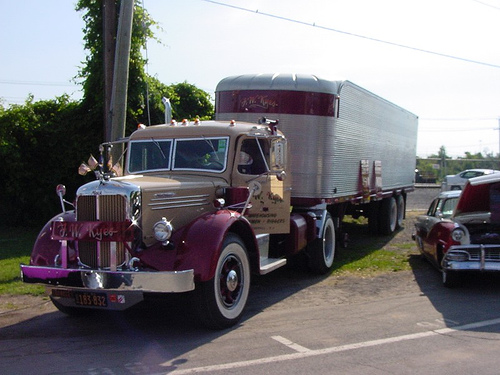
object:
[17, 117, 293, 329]
tractor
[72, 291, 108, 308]
plates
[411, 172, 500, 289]
classic car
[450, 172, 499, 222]
hood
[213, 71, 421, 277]
trailer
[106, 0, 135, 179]
poles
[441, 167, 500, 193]
car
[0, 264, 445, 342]
dirt patch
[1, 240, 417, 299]
grass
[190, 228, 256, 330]
driver's steer tire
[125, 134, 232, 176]
split windshield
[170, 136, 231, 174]
left pane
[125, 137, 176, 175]
right pane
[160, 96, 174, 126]
exhaust pipe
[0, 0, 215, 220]
vines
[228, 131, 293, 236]
open door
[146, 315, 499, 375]
parking lines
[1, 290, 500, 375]
tarmac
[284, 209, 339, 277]
drive tire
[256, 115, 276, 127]
air horn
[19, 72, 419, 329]
tractor-trailer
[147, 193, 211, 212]
chrome trim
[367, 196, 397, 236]
trailer tires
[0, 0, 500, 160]
sky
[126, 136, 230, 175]
trim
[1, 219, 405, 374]
shadow